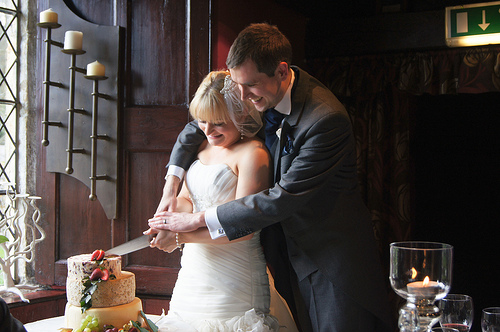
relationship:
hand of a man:
[147, 210, 204, 230] [227, 26, 389, 330]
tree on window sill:
[0, 185, 47, 303] [0, 252, 67, 324]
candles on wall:
[28, 5, 112, 105] [8, 10, 432, 310]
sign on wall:
[440, 6, 498, 43] [35, 0, 499, 332]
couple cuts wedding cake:
[140, 22, 401, 332] [60, 247, 144, 322]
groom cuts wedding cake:
[148, 26, 388, 323] [60, 247, 144, 322]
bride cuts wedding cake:
[149, 74, 272, 329] [60, 247, 144, 322]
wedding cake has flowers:
[63, 246, 143, 330] [88, 246, 110, 281]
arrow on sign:
[474, 7, 494, 35] [441, 2, 498, 48]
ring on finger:
[158, 215, 181, 225] [137, 210, 169, 231]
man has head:
[143, 21, 375, 329] [225, 24, 295, 109]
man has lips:
[204, 17, 329, 230] [250, 92, 262, 105]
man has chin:
[143, 21, 375, 329] [249, 102, 269, 112]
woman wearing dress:
[143, 70, 278, 332] [154, 154, 278, 330]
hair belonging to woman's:
[188, 65, 253, 125] [153, 68, 280, 330]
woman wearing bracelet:
[143, 70, 278, 332] [169, 228, 186, 252]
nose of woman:
[200, 120, 219, 138] [174, 83, 311, 261]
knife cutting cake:
[44, 228, 159, 330] [52, 230, 144, 328]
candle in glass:
[406, 276, 441, 295] [373, 238, 469, 327]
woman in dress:
[152, 76, 269, 329] [154, 154, 278, 330]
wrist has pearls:
[170, 232, 190, 247] [170, 231, 191, 254]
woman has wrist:
[143, 70, 278, 332] [170, 232, 190, 247]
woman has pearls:
[143, 70, 278, 332] [170, 231, 191, 254]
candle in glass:
[374, 249, 478, 320] [388, 235, 456, 329]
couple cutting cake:
[56, 22, 375, 330] [53, 262, 143, 330]